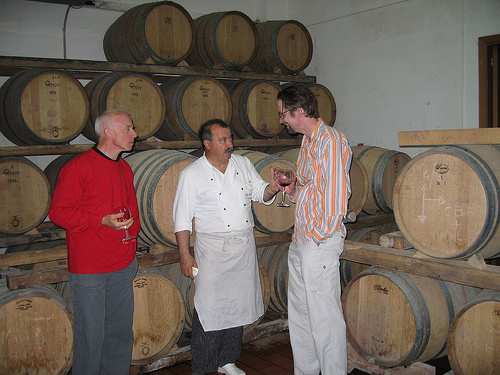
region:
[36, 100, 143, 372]
person holding a wine glass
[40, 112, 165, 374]
person wearing red shirt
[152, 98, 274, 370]
person wearing a white shirt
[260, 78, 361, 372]
person wearing a shirt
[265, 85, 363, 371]
person holding a glass of wine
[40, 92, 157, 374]
person wearing a dark pant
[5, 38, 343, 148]
barrels of wine stacked on a shelf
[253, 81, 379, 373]
person wearing eye glasses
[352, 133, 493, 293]
barrels on a shelf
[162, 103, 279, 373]
person wearing a button shirt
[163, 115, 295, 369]
man wearing white cloths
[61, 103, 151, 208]
man has gray hair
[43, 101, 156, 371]
man wears red top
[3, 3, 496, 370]
people in a winery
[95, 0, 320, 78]
barrels color brown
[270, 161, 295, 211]
a cup of wine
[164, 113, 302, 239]
man holding a cup of red wine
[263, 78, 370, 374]
man wearing a striped shirt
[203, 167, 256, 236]
buttons on a white shirt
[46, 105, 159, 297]
man holding a cup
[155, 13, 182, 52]
The base of a barrel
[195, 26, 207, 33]
Straps around a barrel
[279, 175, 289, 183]
A glass of wine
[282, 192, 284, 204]
The neck of a wine glass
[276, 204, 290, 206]
The base of a glass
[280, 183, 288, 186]
Wine in a glass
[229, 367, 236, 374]
A white shoe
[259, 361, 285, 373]
The floor of the cellar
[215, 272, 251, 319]
A white apron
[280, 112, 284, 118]
Eye glasses on the face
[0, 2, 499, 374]
Many drums in a room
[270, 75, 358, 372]
Man carrying a tall glass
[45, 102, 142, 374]
Man in a red shirt carrying a tall glass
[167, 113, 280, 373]
Man in white work clothes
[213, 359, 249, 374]
Foot in white shoes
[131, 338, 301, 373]
Smooth red brick floor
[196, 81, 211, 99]
Markings on a drum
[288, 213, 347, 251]
Hand stuck in the pocket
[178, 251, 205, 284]
Hand holding an object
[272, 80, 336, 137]
Person wearing a pair of spectacles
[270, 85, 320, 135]
a man with brown hair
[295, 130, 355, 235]
a person in a striped shirt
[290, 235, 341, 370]
a person wearing white pants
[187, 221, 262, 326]
a person wearing a white apron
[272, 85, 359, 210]
a man holding a glass of wine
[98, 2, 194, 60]
an oak wine barrel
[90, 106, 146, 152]
a man with white hair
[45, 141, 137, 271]
a person wearing a red shirt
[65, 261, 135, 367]
a person wearing grey pants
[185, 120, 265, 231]
a man wearing a white shirt